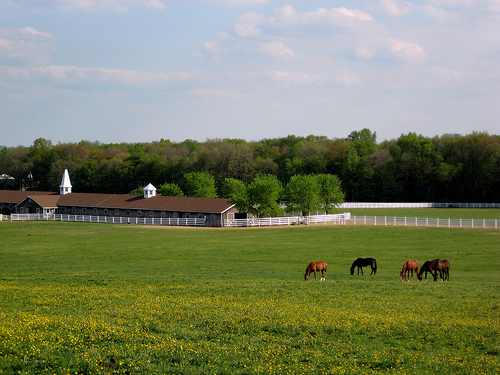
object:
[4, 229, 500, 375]
grass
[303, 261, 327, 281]
horse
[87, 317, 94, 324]
flowers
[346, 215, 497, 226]
fence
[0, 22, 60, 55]
clouds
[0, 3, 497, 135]
sky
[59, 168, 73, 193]
steeple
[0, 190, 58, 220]
house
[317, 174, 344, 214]
tree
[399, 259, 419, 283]
horse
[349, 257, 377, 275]
horse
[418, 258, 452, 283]
horse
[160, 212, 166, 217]
window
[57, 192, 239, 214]
roof